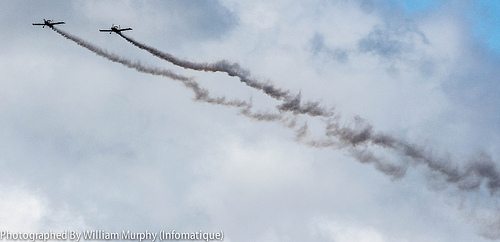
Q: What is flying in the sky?
A: Planes.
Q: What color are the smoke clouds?
A: Gray.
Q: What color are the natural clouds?
A: White.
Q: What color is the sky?
A: Blue.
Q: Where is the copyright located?
A: Left, lower corner.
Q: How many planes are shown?
A: 2.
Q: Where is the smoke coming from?
A: Planes.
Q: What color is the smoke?
A: Dark grey.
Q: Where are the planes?
A: Air.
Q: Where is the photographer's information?
A: Bottom left.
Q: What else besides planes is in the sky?
A: Clouds.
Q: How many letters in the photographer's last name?
A: 6.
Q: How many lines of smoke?
A: 2.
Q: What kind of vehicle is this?
A: Plane.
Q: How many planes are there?
A: Two.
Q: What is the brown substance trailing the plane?
A: Smoke.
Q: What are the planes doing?
A: Flying.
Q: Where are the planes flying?
A: Sky.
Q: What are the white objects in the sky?
A: Clouds.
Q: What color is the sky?
A: Blue and white.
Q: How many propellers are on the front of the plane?
A: One.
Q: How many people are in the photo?
A: None.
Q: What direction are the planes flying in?
A: To the left.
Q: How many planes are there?
A: Two.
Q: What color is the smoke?
A: Black.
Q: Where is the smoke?
A: Behind the plane.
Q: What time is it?
A: Afternoon.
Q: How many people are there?
A: None.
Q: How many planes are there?
A: Two.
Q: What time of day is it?
A: Daytime.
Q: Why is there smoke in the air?
A: From the planes.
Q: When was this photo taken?
A: During the day.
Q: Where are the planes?
A: In the sky.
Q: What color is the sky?
A: Blue.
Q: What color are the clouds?
A: White.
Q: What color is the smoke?
A: Black.